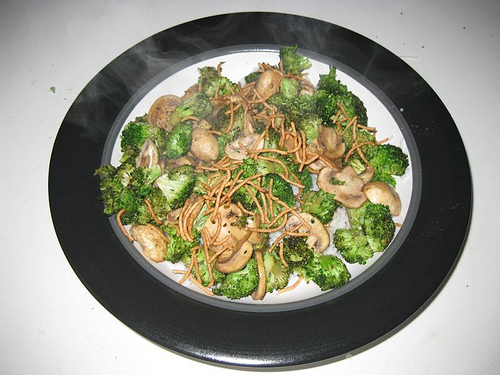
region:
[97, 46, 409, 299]
Broccoli on a plate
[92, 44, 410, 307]
Broccoli is on a plate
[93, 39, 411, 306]
Broccoli on a black and white plate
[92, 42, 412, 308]
Broccoli is on a black and white plate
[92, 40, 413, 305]
Broccoli on a round plate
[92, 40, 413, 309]
Broccoli is on a round plate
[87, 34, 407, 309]
Broccoli on a round black and white plate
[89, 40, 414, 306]
Broccoli is on a round black and white plate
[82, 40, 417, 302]
Mushrooms on a plate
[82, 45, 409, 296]
Mushrooms are on a plate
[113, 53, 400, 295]
a plate of steaming veggies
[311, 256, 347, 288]
a green piece of broccoli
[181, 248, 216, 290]
golden brown noodles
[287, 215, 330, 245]
golden brown mushrooms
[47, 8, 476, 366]
a black plate of veggies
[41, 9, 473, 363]
a bowl of steaming veggies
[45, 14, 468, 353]
a vegetarian dinner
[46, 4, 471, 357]
a bowl of hot vegetables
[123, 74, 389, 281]
a sizzling dish of veggies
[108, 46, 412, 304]
broccoli mushrooms and noodles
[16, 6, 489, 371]
plate of just cooked food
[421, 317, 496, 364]
white table top surface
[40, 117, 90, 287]
edge of a round, black plate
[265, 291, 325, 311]
gray and white inner plate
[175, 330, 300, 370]
glare off the plate's surface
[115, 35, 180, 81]
steam rising off the dish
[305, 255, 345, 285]
cooked green broccoli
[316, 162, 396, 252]
cooked mushrooms and broccoli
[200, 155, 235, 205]
thin cooked noodles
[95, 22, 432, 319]
vegetarian dish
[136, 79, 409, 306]
green broccoli in plate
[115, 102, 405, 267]
brown mushrooms on plate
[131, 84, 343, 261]
sesame noodles on plate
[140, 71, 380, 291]
stir fry on plate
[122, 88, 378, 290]
plate is white and round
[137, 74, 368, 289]
plate has grey border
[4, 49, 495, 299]
plate has black border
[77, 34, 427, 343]
plate on white table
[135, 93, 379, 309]
broccoli is dark green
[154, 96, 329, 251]
crunchy chow mein noodles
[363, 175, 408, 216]
cut and cooked mushroom on a plate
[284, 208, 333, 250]
cut and cooked mushroom on a plate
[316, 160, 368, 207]
cut and cooked mushroom on a plate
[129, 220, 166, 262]
cut and cooked mushroom on a plate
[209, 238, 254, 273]
cut and cooked mushroom on a plate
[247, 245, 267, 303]
cut and cooked mushroom on a plate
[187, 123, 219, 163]
cut and cooked mushroom on a plate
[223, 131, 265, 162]
cut and cooked mushroom on a plate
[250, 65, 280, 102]
cut and cooked mushroom on a plate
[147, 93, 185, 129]
cut and cooked mushroom on a plate